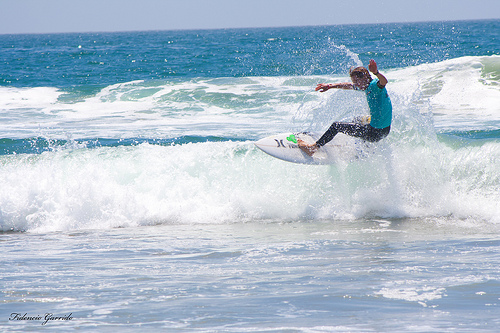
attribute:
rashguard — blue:
[360, 76, 392, 128]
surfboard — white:
[256, 126, 329, 168]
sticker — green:
[284, 130, 305, 152]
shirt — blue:
[351, 79, 393, 126]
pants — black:
[307, 110, 387, 154]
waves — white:
[10, 56, 482, 239]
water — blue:
[6, 17, 484, 327]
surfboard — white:
[246, 128, 396, 164]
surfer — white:
[300, 58, 393, 160]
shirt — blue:
[348, 75, 396, 127]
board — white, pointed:
[256, 127, 381, 164]